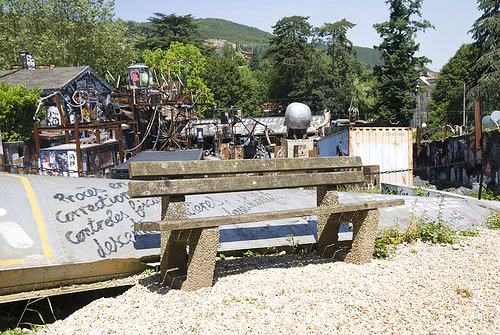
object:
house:
[0, 52, 132, 131]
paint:
[0, 172, 499, 270]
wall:
[36, 95, 60, 130]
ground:
[0, 223, 500, 335]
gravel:
[292, 278, 298, 283]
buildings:
[195, 31, 252, 68]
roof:
[0, 51, 104, 93]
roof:
[173, 117, 280, 136]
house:
[177, 113, 329, 161]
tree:
[312, 17, 368, 124]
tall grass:
[14, 283, 57, 333]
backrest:
[127, 155, 364, 215]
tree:
[421, 0, 499, 141]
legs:
[159, 220, 191, 290]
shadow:
[130, 224, 383, 296]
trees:
[0, 0, 497, 142]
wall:
[350, 125, 418, 182]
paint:
[350, 142, 405, 165]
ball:
[279, 101, 314, 130]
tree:
[201, 50, 247, 116]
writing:
[51, 180, 159, 255]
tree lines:
[0, 0, 500, 144]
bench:
[125, 155, 404, 291]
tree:
[366, 0, 438, 128]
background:
[0, 0, 500, 335]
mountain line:
[184, 17, 267, 44]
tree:
[257, 13, 335, 119]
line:
[10, 168, 74, 284]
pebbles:
[42, 234, 500, 335]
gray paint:
[35, 177, 50, 198]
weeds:
[370, 199, 499, 252]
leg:
[155, 229, 220, 290]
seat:
[133, 192, 409, 230]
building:
[171, 107, 416, 186]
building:
[0, 50, 197, 180]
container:
[315, 124, 414, 189]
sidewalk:
[3, 167, 172, 273]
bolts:
[161, 172, 172, 188]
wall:
[4, 168, 373, 278]